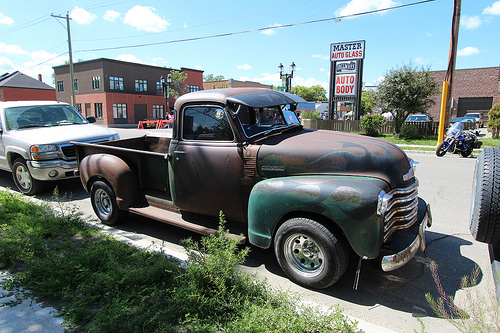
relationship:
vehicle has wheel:
[62, 80, 434, 294] [276, 216, 341, 298]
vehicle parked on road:
[62, 80, 434, 294] [0, 125, 500, 333]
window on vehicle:
[179, 105, 234, 143] [62, 80, 434, 294]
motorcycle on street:
[436, 120, 479, 159] [45, 124, 494, 328]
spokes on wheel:
[283, 230, 327, 277] [270, 213, 347, 291]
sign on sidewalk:
[331, 41, 361, 101] [395, 141, 483, 148]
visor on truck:
[232, 88, 298, 110] [154, 90, 393, 226]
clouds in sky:
[96, 4, 168, 38] [186, 5, 246, 41]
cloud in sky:
[330, 0, 402, 20] [16, 10, 485, 79]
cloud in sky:
[331, 2, 394, 13] [0, 1, 498, 86]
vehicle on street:
[69, 86, 435, 292] [1, 150, 499, 332]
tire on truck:
[467, 146, 499, 244] [469, 133, 500, 303]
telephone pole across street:
[64, 11, 81, 104] [432, 157, 468, 250]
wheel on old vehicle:
[270, 215, 353, 290] [69, 86, 435, 292]